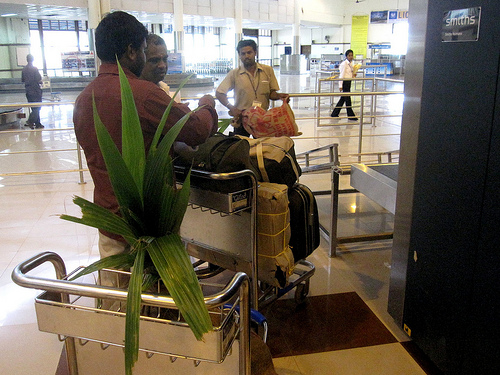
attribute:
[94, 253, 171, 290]
basket — metal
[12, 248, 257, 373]
luggage cart — silver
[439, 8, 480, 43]
sign — small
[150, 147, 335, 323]
roller — metal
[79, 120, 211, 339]
plant — green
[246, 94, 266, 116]
badge — Identification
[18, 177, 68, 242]
floor — tiled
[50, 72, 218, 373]
plant — green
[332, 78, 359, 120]
pants — black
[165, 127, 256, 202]
duffel — dark, green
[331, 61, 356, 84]
blouse — white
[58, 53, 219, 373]
plant — green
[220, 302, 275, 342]
handle — metal, blue, silver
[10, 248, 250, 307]
handle — silver, metal, blue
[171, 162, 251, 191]
handle — silver, metal, blue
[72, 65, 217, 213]
shirt — maroon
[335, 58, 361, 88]
shirt — white